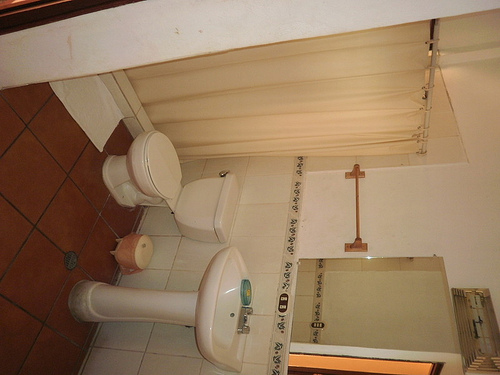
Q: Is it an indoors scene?
A: Yes, it is indoors.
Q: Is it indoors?
A: Yes, it is indoors.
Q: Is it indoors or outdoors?
A: It is indoors.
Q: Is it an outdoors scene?
A: No, it is indoors.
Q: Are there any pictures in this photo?
A: No, there are no pictures.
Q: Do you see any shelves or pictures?
A: No, there are no pictures or shelves.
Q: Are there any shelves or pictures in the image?
A: No, there are no pictures or shelves.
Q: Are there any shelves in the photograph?
A: No, there are no shelves.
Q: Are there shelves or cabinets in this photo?
A: No, there are no shelves or cabinets.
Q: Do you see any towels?
A: Yes, there is a towel.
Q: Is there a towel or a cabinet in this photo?
A: Yes, there is a towel.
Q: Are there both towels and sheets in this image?
A: No, there is a towel but no sheets.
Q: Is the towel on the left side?
A: Yes, the towel is on the left of the image.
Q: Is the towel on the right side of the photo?
A: No, the towel is on the left of the image.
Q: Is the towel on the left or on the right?
A: The towel is on the left of the image.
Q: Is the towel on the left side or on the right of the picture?
A: The towel is on the left of the image.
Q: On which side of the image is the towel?
A: The towel is on the left of the image.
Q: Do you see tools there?
A: No, there are no tools.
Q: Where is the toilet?
A: The toilet is in the bathroom.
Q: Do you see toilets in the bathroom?
A: Yes, there is a toilet in the bathroom.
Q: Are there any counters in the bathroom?
A: No, there is a toilet in the bathroom.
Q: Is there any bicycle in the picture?
A: No, there are no bicycles.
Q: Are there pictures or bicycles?
A: No, there are no bicycles or pictures.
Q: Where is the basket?
A: The basket is on the floor.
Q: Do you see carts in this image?
A: No, there are no carts.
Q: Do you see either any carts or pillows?
A: No, there are no carts or pillows.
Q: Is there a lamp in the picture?
A: No, there are no lamps.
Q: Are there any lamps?
A: No, there are no lamps.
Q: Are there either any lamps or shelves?
A: No, there are no lamps or shelves.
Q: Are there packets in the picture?
A: No, there are no packets.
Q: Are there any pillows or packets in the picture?
A: No, there are no packets or pillows.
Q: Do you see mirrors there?
A: Yes, there is a mirror.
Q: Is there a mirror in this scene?
A: Yes, there is a mirror.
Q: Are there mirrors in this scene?
A: Yes, there is a mirror.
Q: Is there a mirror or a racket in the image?
A: Yes, there is a mirror.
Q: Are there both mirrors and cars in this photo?
A: No, there is a mirror but no cars.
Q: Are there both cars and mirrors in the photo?
A: No, there is a mirror but no cars.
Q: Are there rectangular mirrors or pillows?
A: Yes, there is a rectangular mirror.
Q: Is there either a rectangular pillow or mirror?
A: Yes, there is a rectangular mirror.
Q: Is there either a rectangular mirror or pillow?
A: Yes, there is a rectangular mirror.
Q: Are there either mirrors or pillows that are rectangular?
A: Yes, the mirror is rectangular.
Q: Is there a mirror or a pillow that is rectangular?
A: Yes, the mirror is rectangular.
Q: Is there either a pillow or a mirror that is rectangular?
A: Yes, the mirror is rectangular.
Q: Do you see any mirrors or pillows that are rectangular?
A: Yes, the mirror is rectangular.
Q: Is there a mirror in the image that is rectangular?
A: Yes, there is a rectangular mirror.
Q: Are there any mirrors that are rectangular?
A: Yes, there is a mirror that is rectangular.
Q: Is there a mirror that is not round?
A: Yes, there is a rectangular mirror.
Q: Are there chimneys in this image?
A: No, there are no chimneys.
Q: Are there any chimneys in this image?
A: No, there are no chimneys.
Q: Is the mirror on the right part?
A: Yes, the mirror is on the right of the image.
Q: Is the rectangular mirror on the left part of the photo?
A: No, the mirror is on the right of the image.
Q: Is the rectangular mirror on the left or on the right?
A: The mirror is on the right of the image.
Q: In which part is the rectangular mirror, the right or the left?
A: The mirror is on the right of the image.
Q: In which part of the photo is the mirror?
A: The mirror is on the right of the image.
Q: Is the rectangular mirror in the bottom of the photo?
A: Yes, the mirror is in the bottom of the image.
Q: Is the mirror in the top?
A: No, the mirror is in the bottom of the image.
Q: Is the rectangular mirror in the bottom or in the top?
A: The mirror is in the bottom of the image.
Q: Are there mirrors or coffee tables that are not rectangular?
A: No, there is a mirror but it is rectangular.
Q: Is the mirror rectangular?
A: Yes, the mirror is rectangular.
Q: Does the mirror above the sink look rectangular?
A: Yes, the mirror is rectangular.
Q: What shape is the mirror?
A: The mirror is rectangular.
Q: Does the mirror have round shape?
A: No, the mirror is rectangular.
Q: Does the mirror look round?
A: No, the mirror is rectangular.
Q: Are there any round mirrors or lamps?
A: No, there is a mirror but it is rectangular.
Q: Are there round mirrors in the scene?
A: No, there is a mirror but it is rectangular.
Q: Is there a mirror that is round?
A: No, there is a mirror but it is rectangular.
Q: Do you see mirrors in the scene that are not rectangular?
A: No, there is a mirror but it is rectangular.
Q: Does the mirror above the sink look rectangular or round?
A: The mirror is rectangular.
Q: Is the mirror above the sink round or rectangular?
A: The mirror is rectangular.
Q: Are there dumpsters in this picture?
A: No, there are no dumpsters.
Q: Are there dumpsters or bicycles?
A: No, there are no dumpsters or bicycles.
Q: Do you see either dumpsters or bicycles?
A: No, there are no dumpsters or bicycles.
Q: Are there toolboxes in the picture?
A: No, there are no toolboxes.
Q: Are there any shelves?
A: No, there are no shelves.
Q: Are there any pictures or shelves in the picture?
A: No, there are no shelves or pictures.